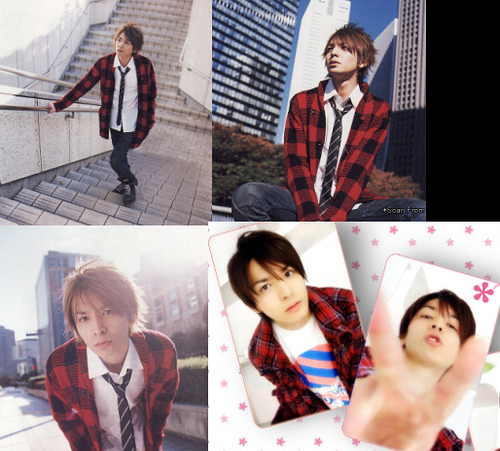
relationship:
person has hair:
[47, 23, 162, 206] [113, 23, 145, 55]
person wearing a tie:
[47, 23, 162, 206] [116, 64, 130, 128]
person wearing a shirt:
[47, 23, 162, 206] [83, 348, 149, 451]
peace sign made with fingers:
[366, 291, 481, 400] [352, 290, 483, 450]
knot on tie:
[117, 72, 132, 78] [116, 64, 130, 128]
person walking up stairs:
[47, 23, 162, 206] [3, 147, 212, 222]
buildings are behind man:
[212, 1, 424, 199] [225, 22, 433, 220]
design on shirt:
[289, 344, 340, 392] [272, 320, 353, 408]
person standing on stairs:
[47, 23, 162, 206] [3, 147, 212, 222]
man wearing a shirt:
[225, 22, 433, 220] [284, 76, 395, 222]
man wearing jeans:
[225, 22, 433, 220] [226, 181, 427, 221]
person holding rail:
[47, 23, 162, 206] [1, 67, 106, 118]